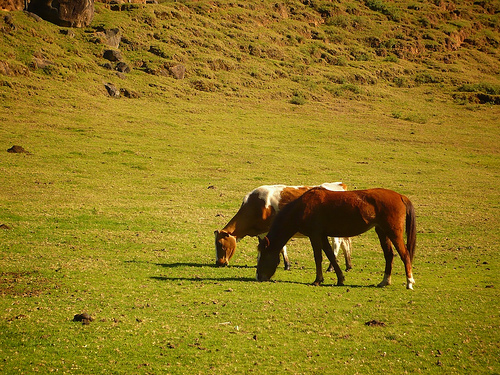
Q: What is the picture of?
A: Two animals grazing on a field.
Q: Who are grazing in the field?
A: A horse and a cow.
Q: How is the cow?
A: Brown and white cow is eating grass.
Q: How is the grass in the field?
A: Green and short.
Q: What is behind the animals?
A: A grassy hill.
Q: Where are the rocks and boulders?
A: On the slope of the hill.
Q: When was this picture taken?
A: During daytime.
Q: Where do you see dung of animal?
A: On the grass.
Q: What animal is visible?
A: Horses.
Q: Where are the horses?
A: In a field.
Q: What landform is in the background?
A: Hill.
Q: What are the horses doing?
A: Grazing.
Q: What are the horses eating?
A: Grass.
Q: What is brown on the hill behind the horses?
A: Rocks.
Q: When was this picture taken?
A: During the daytime.